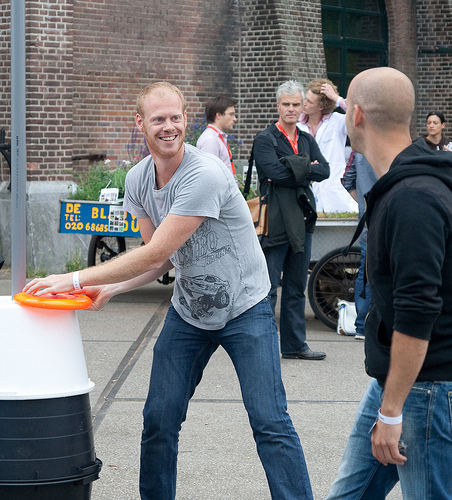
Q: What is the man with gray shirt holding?
A: A frisbee.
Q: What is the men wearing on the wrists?
A: White bands.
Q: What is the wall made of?
A: Bricks.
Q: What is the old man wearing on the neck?
A: Lanyards.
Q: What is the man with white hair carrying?
A: A jacket.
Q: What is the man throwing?
A: Frisbee.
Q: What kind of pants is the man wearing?
A: Jeans.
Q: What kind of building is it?
A: Brick.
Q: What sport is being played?
A: Frisbee.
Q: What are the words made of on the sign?
A: Blue and yellow.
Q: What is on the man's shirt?
A: A picture.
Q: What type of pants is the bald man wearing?
A: Blue jeans.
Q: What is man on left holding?
A: Frisbee.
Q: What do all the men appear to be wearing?
A: Jeans.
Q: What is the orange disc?
A: Frisbee.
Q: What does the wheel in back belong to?
A: Cart.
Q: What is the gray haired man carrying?
A: Jacket.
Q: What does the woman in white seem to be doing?
A: Fixing hair.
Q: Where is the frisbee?
A: On overturned trash can.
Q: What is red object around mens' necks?
A: Lanyards.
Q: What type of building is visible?
A: Brick.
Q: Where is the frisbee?
A: In hands of man in grey shirt.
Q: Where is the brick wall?
A: Behind people.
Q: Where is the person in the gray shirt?
A: Left.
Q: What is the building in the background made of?
A: Bricks.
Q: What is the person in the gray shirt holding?
A: Frisbee.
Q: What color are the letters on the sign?
A: Yellow.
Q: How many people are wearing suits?
A: 1.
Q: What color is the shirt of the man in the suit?
A: Red.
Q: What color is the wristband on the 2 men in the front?
A: White.